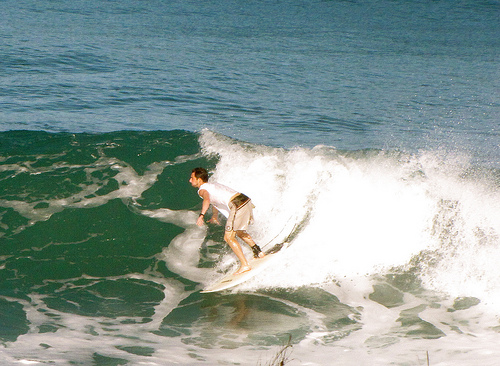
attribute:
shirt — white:
[197, 179, 241, 217]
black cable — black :
[250, 243, 262, 256]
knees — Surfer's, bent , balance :
[225, 226, 251, 243]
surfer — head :
[182, 148, 211, 185]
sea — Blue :
[5, 6, 489, 143]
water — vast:
[207, 38, 370, 86]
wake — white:
[191, 132, 455, 292]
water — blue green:
[34, 77, 154, 246]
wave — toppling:
[251, 151, 476, 253]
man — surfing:
[187, 167, 266, 280]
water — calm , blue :
[0, 1, 500, 364]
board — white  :
[201, 247, 276, 289]